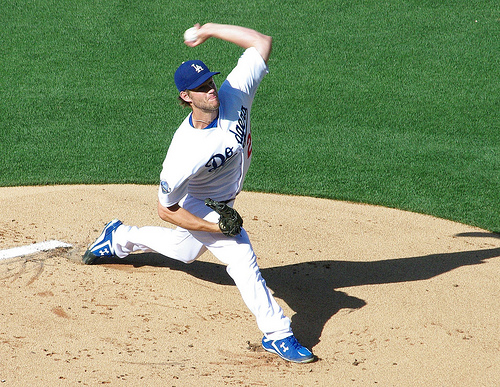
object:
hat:
[172, 59, 218, 89]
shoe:
[260, 335, 317, 364]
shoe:
[82, 217, 122, 265]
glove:
[205, 198, 244, 239]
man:
[81, 22, 317, 366]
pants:
[112, 196, 294, 341]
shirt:
[157, 46, 270, 207]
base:
[0, 183, 500, 387]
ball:
[183, 27, 200, 44]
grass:
[10, 8, 500, 233]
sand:
[13, 194, 367, 373]